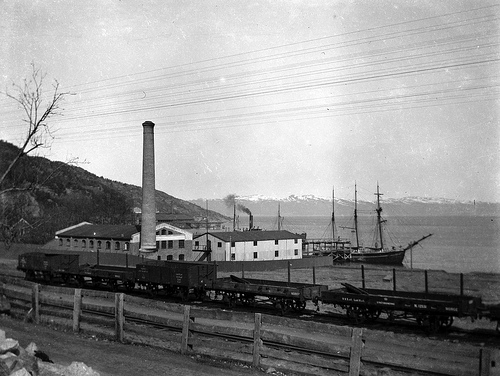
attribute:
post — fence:
[165, 300, 197, 353]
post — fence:
[30, 283, 42, 328]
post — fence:
[68, 284, 81, 337]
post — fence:
[111, 293, 128, 340]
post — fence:
[179, 304, 195, 359]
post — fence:
[250, 314, 262, 374]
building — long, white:
[187, 225, 309, 264]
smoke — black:
[222, 194, 249, 216]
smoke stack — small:
[244, 216, 256, 229]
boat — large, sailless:
[307, 179, 440, 279]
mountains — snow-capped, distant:
[241, 189, 498, 226]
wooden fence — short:
[0, 274, 497, 374]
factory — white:
[185, 222, 312, 272]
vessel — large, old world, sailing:
[318, 181, 432, 263]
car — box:
[16, 249, 78, 283]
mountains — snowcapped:
[196, 192, 498, 219]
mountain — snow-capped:
[341, 170, 480, 251]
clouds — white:
[251, 117, 446, 177]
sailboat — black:
[291, 169, 448, 283]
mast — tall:
[344, 179, 381, 250]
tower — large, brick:
[131, 118, 175, 253]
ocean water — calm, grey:
[245, 218, 498, 275]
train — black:
[16, 248, 498, 343]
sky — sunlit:
[1, 2, 499, 205]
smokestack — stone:
[138, 115, 157, 251]